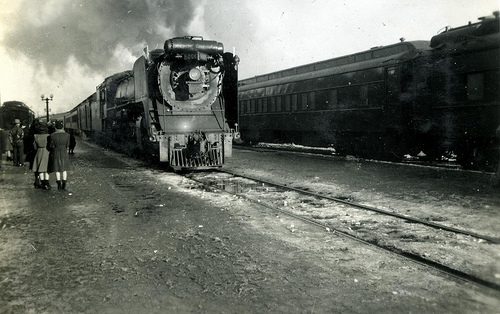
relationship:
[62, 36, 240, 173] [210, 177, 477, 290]
train on track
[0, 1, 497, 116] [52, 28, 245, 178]
sky above train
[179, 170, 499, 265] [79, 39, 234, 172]
puddle below train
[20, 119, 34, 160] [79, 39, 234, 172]
persons by train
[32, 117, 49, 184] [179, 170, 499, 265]
persons by puddle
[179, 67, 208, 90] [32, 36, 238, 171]
light by train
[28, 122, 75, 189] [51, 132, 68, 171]
women wearing dresss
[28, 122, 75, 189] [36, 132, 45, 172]
women wearing dresss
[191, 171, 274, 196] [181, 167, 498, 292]
puddle on top tracks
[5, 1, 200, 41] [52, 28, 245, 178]
steam coming train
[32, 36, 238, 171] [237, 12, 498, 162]
train passing train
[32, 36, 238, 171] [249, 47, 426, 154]
train passing cars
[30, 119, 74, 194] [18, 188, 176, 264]
women standing ground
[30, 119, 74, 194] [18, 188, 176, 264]
women waiting ground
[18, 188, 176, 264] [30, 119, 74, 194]
ground with women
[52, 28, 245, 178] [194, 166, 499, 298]
train with track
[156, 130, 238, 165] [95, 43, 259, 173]
headlight on train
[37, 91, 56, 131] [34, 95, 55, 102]
pole with lights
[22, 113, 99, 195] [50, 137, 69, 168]
women with jackets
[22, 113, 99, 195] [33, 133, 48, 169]
women with jackets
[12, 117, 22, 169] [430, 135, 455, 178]
man walking ground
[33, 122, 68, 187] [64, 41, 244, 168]
people in train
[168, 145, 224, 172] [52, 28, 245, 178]
safety ram in train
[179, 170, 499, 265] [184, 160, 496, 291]
puddle on ground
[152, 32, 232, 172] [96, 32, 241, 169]
front of engine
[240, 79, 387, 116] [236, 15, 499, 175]
windows on side of train